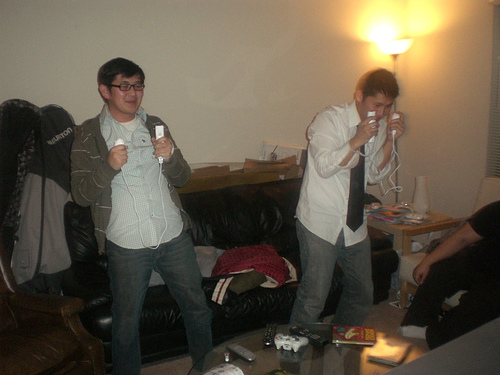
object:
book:
[330, 326, 377, 347]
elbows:
[307, 143, 350, 177]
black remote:
[262, 320, 275, 347]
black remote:
[289, 323, 329, 346]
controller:
[114, 138, 124, 144]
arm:
[423, 201, 499, 266]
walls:
[2, 2, 499, 199]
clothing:
[148, 244, 300, 306]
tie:
[346, 146, 365, 233]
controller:
[273, 333, 309, 352]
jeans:
[105, 238, 215, 373]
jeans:
[295, 216, 374, 326]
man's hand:
[385, 119, 404, 141]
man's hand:
[150, 137, 172, 164]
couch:
[0, 176, 399, 375]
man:
[401, 204, 499, 351]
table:
[366, 201, 468, 307]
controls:
[154, 124, 165, 163]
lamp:
[361, 3, 451, 90]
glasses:
[103, 82, 145, 92]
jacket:
[68, 113, 191, 258]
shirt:
[296, 104, 398, 246]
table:
[188, 318, 426, 375]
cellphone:
[227, 341, 257, 363]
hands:
[357, 116, 380, 146]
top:
[362, 3, 430, 38]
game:
[364, 110, 402, 195]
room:
[8, 5, 488, 373]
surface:
[363, 196, 455, 227]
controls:
[391, 112, 399, 135]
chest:
[349, 134, 403, 195]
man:
[293, 68, 408, 328]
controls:
[366, 110, 375, 144]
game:
[113, 124, 171, 250]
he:
[69, 57, 215, 374]